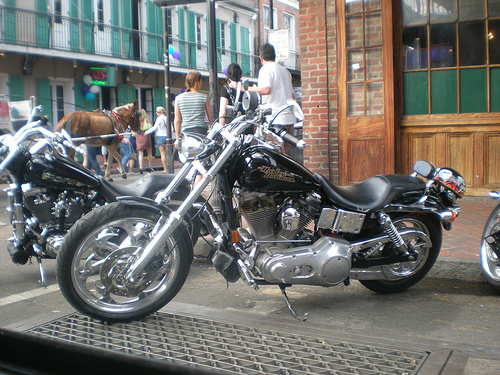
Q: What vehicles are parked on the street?
A: Motorcycles.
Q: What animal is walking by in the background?
A: A brown horse.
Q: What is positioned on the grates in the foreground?
A: The front wheel of the motorcycle.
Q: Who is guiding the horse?
A: A woman.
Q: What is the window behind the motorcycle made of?
A: A wooden window.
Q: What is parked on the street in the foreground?
A: Two black and chrome motorcycles.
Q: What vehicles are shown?
A: Motorcycles.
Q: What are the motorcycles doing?
A: Parked.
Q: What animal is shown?
A: Horse.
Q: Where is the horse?
A: In the street.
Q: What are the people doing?
A: Standing.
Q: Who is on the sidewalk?
A: Pedestrians.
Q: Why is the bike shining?
A: The sun is reflecting.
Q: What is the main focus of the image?
A: A motorcycle.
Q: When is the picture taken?
A: Daytime.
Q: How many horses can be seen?
A: 1.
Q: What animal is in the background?
A: A horse.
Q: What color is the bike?
A: Black.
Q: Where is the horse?
A: In the street.